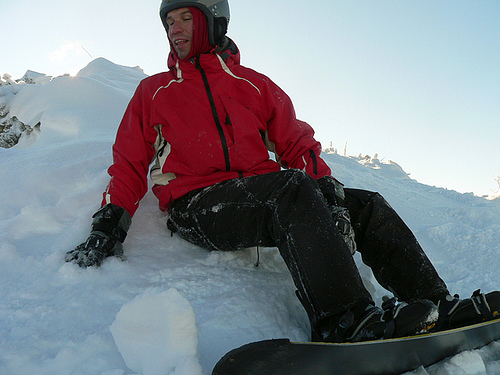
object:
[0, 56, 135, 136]
mountain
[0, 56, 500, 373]
snow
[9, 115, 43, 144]
rocks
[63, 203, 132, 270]
glove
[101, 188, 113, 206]
label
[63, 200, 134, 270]
hand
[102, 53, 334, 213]
jacket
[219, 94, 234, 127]
mark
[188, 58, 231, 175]
zipper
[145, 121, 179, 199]
cut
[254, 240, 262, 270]
string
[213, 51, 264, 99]
line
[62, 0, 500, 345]
man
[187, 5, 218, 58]
scarf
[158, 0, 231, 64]
head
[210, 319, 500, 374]
snowboard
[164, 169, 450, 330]
pants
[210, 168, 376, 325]
leg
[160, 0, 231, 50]
helmet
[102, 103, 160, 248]
arm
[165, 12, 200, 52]
face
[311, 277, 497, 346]
feet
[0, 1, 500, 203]
sky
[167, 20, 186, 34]
nose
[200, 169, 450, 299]
legs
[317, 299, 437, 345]
boot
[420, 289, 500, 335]
boot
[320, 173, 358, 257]
glove